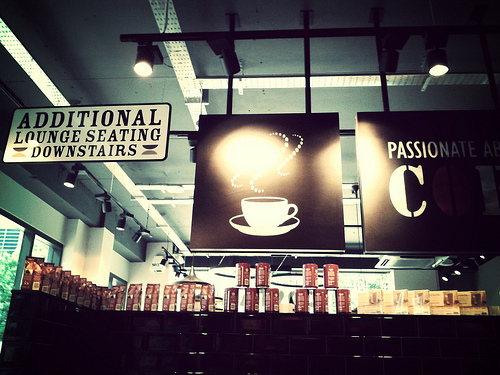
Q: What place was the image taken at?
A: It was taken at the restaurant.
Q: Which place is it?
A: It is a restaurant.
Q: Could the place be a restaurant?
A: Yes, it is a restaurant.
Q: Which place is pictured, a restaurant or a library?
A: It is a restaurant.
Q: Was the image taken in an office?
A: No, the picture was taken in a restaurant.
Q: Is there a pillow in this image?
A: No, there are no pillows.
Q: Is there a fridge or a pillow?
A: No, there are no pillows or refrigerators.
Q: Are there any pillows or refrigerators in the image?
A: No, there are no pillows or refrigerators.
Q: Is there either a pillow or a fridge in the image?
A: No, there are no pillows or refrigerators.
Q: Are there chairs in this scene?
A: No, there are no chairs.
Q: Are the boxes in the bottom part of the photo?
A: Yes, the boxes are in the bottom of the image.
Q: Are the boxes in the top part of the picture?
A: No, the boxes are in the bottom of the image.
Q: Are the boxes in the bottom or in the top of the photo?
A: The boxes are in the bottom of the image.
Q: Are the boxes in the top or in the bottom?
A: The boxes are in the bottom of the image.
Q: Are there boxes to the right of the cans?
A: Yes, there are boxes to the right of the cans.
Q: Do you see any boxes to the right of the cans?
A: Yes, there are boxes to the right of the cans.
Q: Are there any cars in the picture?
A: No, there are no cars.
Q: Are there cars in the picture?
A: No, there are no cars.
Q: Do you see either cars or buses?
A: No, there are no cars or buses.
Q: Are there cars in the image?
A: No, there are no cars.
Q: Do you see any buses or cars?
A: No, there are no cars or buses.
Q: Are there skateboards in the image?
A: No, there are no skateboards.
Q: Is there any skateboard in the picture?
A: No, there are no skateboards.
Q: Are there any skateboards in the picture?
A: No, there are no skateboards.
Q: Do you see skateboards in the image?
A: No, there are no skateboards.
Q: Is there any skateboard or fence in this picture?
A: No, there are no skateboards or fences.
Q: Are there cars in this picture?
A: No, there are no cars.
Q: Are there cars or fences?
A: No, there are no cars or fences.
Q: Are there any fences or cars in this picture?
A: No, there are no cars or fences.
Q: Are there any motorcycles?
A: No, there are no motorcycles.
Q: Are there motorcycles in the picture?
A: No, there are no motorcycles.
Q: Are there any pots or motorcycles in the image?
A: No, there are no motorcycles or pots.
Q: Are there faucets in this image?
A: No, there are no faucets.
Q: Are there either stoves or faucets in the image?
A: No, there are no faucets or stoves.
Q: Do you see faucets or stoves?
A: No, there are no faucets or stoves.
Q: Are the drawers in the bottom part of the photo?
A: Yes, the drawers are in the bottom of the image.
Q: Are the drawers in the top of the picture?
A: No, the drawers are in the bottom of the image.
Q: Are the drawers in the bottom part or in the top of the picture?
A: The drawers are in the bottom of the image.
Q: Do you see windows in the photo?
A: Yes, there is a window.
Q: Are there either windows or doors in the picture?
A: Yes, there is a window.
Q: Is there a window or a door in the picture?
A: Yes, there is a window.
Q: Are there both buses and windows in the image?
A: No, there is a window but no buses.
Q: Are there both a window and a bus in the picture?
A: No, there is a window but no buses.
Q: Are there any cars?
A: No, there are no cars.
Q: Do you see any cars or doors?
A: No, there are no cars or doors.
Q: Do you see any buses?
A: No, there are no buses.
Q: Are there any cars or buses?
A: No, there are no buses or cars.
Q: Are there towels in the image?
A: No, there are no towels.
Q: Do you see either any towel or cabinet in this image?
A: No, there are no towels or cabinets.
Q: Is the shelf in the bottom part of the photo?
A: Yes, the shelf is in the bottom of the image.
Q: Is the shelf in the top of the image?
A: No, the shelf is in the bottom of the image.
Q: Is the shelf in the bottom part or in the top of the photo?
A: The shelf is in the bottom of the image.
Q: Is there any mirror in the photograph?
A: No, there are no mirrors.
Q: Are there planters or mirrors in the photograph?
A: No, there are no mirrors or planters.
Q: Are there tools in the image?
A: No, there are no tools.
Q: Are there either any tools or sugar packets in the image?
A: No, there are no tools or sugar packets.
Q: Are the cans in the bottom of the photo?
A: Yes, the cans are in the bottom of the image.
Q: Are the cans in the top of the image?
A: No, the cans are in the bottom of the image.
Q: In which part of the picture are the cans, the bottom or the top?
A: The cans are in the bottom of the image.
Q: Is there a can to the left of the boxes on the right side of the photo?
A: Yes, there are cans to the left of the boxes.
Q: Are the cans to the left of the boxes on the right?
A: Yes, the cans are to the left of the boxes.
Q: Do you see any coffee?
A: Yes, there is coffee.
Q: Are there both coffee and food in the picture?
A: No, there is coffee but no food.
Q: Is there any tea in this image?
A: No, there is no tea.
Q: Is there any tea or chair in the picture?
A: No, there are no tea or chairs.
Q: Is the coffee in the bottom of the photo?
A: Yes, the coffee is in the bottom of the image.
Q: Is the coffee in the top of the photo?
A: No, the coffee is in the bottom of the image.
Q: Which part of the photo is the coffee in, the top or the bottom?
A: The coffee is in the bottom of the image.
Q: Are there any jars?
A: No, there are no jars.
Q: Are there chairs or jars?
A: No, there are no jars or chairs.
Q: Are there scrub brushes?
A: No, there are no scrub brushes.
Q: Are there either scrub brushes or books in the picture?
A: No, there are no scrub brushes or books.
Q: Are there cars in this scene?
A: No, there are no cars.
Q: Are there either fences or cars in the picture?
A: No, there are no cars or fences.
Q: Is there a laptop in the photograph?
A: No, there are no laptops.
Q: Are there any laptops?
A: No, there are no laptops.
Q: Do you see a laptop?
A: No, there are no laptops.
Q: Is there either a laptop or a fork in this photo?
A: No, there are no laptops or forks.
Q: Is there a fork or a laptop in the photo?
A: No, there are no laptops or forks.